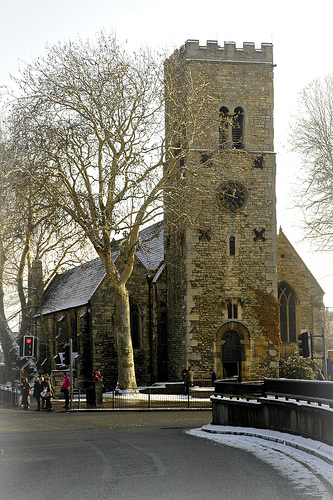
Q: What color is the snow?
A: White.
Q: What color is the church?
A: Brown.